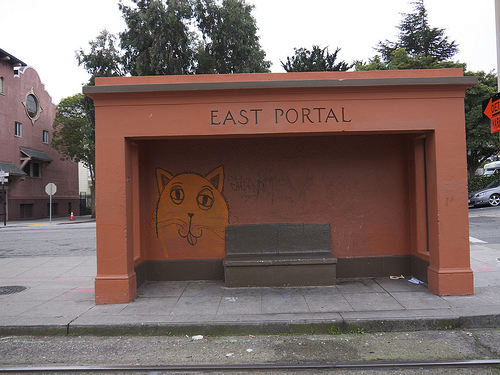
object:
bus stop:
[80, 67, 485, 304]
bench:
[222, 220, 339, 286]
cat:
[153, 165, 232, 258]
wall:
[141, 142, 417, 258]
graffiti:
[225, 172, 335, 205]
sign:
[475, 88, 499, 135]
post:
[486, 5, 500, 51]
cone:
[69, 211, 75, 221]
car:
[465, 184, 500, 208]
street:
[467, 207, 499, 251]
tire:
[487, 192, 499, 206]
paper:
[406, 276, 425, 286]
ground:
[147, 275, 430, 316]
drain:
[1, 281, 28, 296]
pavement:
[3, 256, 100, 317]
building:
[0, 49, 79, 225]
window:
[22, 85, 44, 123]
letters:
[206, 102, 372, 126]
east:
[208, 108, 263, 126]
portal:
[267, 105, 355, 124]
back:
[44, 181, 57, 195]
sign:
[42, 179, 60, 223]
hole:
[465, 330, 497, 361]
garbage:
[191, 332, 205, 343]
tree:
[115, 1, 209, 82]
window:
[12, 117, 26, 140]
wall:
[122, 77, 425, 128]